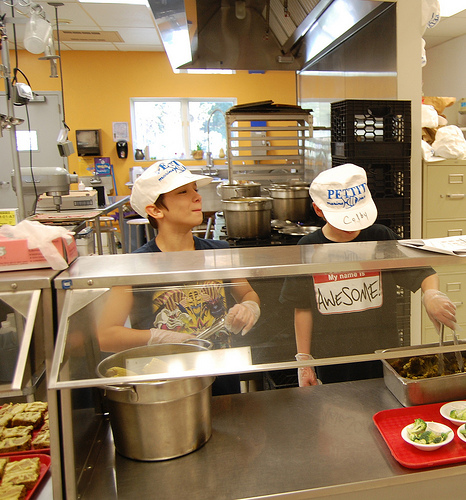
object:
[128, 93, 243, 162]
window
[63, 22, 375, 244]
building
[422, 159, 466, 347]
beige cabinet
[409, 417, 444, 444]
broccoli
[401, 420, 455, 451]
dish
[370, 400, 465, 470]
cafeteria tray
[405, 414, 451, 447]
lemons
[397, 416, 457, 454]
plate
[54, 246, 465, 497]
case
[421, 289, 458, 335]
glove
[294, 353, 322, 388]
glove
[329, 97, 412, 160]
milk container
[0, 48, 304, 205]
wall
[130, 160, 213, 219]
cap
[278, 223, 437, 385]
t-shirt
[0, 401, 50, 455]
bread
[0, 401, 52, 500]
tray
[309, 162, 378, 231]
cap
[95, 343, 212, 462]
cooking pot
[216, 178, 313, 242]
pots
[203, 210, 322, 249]
stove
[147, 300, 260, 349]
gloves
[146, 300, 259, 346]
hands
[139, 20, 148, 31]
ceiling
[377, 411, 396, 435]
red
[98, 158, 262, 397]
person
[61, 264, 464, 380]
glass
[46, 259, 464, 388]
shelf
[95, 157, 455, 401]
kids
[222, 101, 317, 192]
tray cart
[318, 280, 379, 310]
awesome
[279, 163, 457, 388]
boy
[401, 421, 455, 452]
bowl